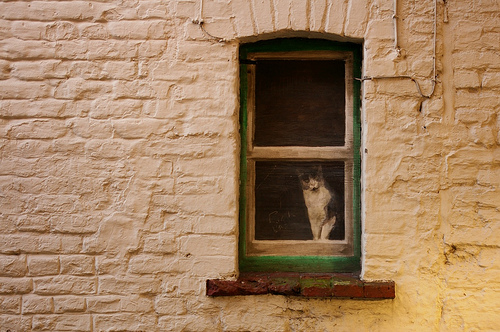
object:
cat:
[293, 160, 345, 238]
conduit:
[389, 2, 402, 52]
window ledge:
[201, 268, 413, 313]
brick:
[363, 277, 398, 302]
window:
[235, 40, 359, 273]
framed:
[209, 281, 359, 332]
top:
[166, 52, 366, 175]